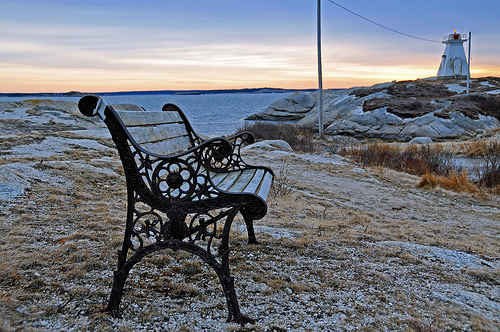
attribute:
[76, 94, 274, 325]
bench — empty, black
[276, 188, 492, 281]
grass — brown, dead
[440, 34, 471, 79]
building — white, distant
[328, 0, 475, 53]
wire — thick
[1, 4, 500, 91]
sky — orange, pretty, above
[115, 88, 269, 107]
water — still, calm, distant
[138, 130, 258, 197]
arm — black